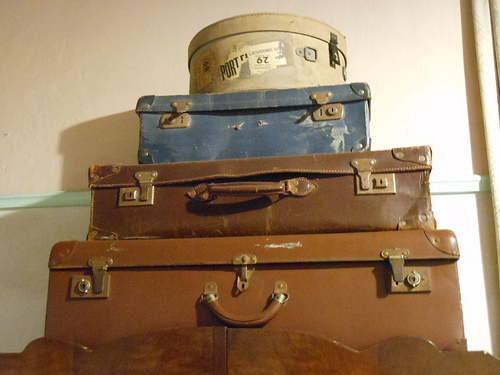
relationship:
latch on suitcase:
[343, 151, 379, 194] [47, 47, 444, 347]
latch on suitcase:
[309, 88, 345, 120] [133, 79, 373, 164]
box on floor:
[42, 223, 467, 350] [0, 340, 484, 360]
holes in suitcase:
[227, 114, 267, 131] [134, 84, 390, 160]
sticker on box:
[213, 44, 290, 84] [186, 10, 349, 93]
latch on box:
[224, 241, 261, 304] [42, 223, 467, 350]